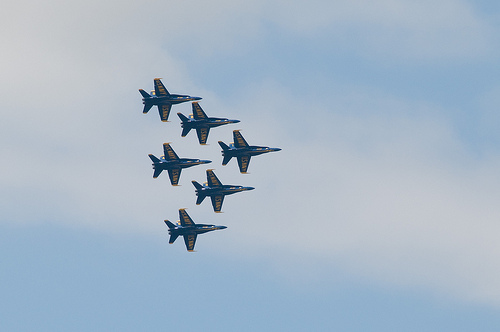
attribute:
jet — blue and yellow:
[160, 204, 228, 256]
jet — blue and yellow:
[188, 163, 260, 213]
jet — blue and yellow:
[147, 135, 212, 192]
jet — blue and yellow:
[212, 125, 282, 176]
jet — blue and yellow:
[176, 93, 239, 146]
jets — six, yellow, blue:
[137, 70, 286, 256]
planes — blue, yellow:
[135, 60, 283, 278]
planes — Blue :
[93, 49, 313, 282]